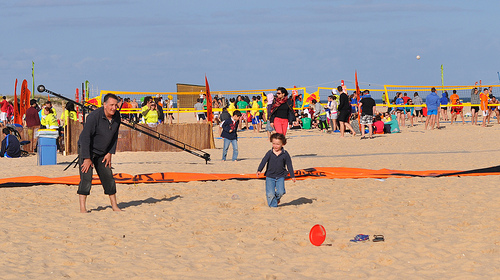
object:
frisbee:
[304, 222, 336, 259]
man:
[58, 83, 139, 219]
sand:
[120, 220, 272, 261]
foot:
[108, 204, 128, 215]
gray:
[85, 114, 115, 153]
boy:
[260, 132, 296, 208]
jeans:
[263, 177, 290, 206]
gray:
[264, 151, 286, 170]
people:
[156, 90, 383, 128]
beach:
[340, 145, 461, 163]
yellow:
[383, 100, 398, 109]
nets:
[381, 83, 496, 110]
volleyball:
[414, 53, 424, 63]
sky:
[58, 15, 434, 44]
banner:
[7, 168, 493, 184]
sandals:
[354, 232, 385, 245]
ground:
[155, 222, 405, 263]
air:
[8, 7, 498, 38]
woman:
[263, 85, 293, 133]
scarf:
[271, 93, 289, 106]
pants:
[273, 117, 294, 132]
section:
[180, 126, 199, 141]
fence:
[72, 119, 207, 146]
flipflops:
[351, 229, 392, 248]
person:
[370, 113, 391, 134]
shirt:
[374, 120, 384, 130]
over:
[96, 141, 99, 145]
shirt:
[84, 103, 114, 144]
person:
[2, 129, 22, 159]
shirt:
[3, 133, 21, 152]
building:
[173, 77, 213, 111]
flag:
[10, 81, 20, 129]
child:
[225, 110, 244, 166]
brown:
[308, 135, 311, 140]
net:
[101, 90, 271, 113]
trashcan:
[32, 127, 63, 168]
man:
[337, 83, 354, 136]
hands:
[81, 157, 113, 171]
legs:
[78, 163, 125, 200]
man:
[428, 83, 442, 131]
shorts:
[425, 108, 440, 117]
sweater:
[81, 108, 126, 153]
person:
[358, 87, 381, 139]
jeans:
[77, 156, 121, 201]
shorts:
[451, 109, 473, 115]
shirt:
[146, 111, 169, 123]